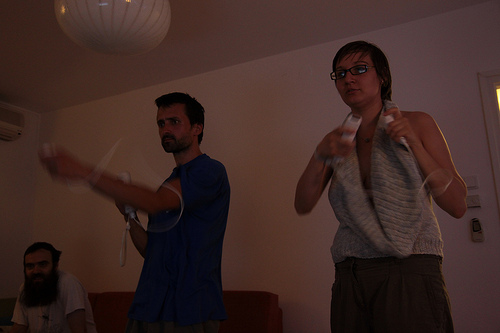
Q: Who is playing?
A: People.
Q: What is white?
A: Wall.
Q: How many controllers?
A: 2.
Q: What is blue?
A: Shirt.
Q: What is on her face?
A: Glasses.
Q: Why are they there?
A: To play.